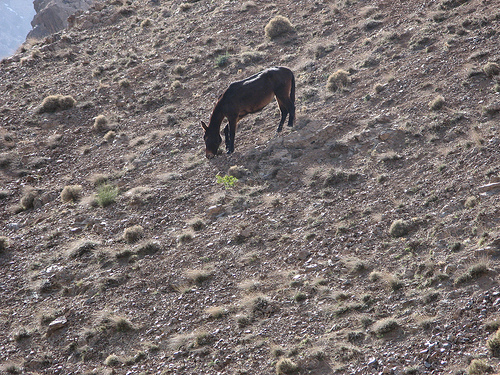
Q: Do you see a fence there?
A: No, there are no fences.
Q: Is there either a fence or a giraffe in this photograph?
A: No, there are no fences or giraffes.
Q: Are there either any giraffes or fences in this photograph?
A: No, there are no fences or giraffes.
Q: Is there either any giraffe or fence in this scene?
A: No, there are no fences or giraffes.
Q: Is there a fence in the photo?
A: No, there are no fences.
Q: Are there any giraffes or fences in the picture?
A: No, there are no fences or giraffes.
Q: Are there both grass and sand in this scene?
A: No, there is grass but no sand.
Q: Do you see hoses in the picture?
A: No, there are no hoses.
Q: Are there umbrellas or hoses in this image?
A: No, there are no hoses or umbrellas.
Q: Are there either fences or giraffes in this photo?
A: No, there are no fences or giraffes.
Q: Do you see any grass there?
A: Yes, there is grass.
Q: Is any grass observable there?
A: Yes, there is grass.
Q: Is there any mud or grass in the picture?
A: Yes, there is grass.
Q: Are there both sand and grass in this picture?
A: No, there is grass but no sand.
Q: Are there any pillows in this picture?
A: No, there are no pillows.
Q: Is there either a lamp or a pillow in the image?
A: No, there are no pillows or lamps.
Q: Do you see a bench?
A: No, there are no benches.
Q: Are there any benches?
A: No, there are no benches.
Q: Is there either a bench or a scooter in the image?
A: No, there are no benches or scooters.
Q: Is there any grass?
A: Yes, there is grass.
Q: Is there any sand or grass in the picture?
A: Yes, there is grass.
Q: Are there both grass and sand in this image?
A: No, there is grass but no sand.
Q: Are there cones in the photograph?
A: No, there are no cones.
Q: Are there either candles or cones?
A: No, there are no cones or candles.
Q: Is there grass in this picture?
A: Yes, there is grass.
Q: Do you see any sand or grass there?
A: Yes, there is grass.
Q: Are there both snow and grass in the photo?
A: No, there is grass but no snow.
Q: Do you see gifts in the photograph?
A: No, there are no gifts.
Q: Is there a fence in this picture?
A: No, there are no fences.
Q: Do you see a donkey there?
A: Yes, there is a donkey.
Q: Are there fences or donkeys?
A: Yes, there is a donkey.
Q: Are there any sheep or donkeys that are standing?
A: Yes, the donkey is standing.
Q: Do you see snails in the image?
A: No, there are no snails.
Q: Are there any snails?
A: No, there are no snails.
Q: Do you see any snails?
A: No, there are no snails.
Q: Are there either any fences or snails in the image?
A: No, there are no snails or fences.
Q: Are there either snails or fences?
A: No, there are no snails or fences.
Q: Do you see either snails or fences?
A: No, there are no snails or fences.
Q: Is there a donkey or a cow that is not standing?
A: No, there is a donkey but it is standing.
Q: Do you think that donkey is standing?
A: Yes, the donkey is standing.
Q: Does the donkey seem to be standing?
A: Yes, the donkey is standing.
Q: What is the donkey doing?
A: The donkey is standing.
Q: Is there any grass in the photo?
A: Yes, there is grass.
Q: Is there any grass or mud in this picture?
A: Yes, there is grass.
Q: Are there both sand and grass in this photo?
A: No, there is grass but no sand.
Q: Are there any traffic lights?
A: No, there are no traffic lights.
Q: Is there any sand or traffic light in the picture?
A: No, there are no traffic lights or sand.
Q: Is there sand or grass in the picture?
A: Yes, there is grass.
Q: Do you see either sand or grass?
A: Yes, there is grass.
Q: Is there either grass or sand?
A: Yes, there is grass.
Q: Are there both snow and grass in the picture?
A: No, there is grass but no snow.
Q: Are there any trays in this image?
A: No, there are no trays.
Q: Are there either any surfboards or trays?
A: No, there are no trays or surfboards.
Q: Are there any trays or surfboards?
A: No, there are no trays or surfboards.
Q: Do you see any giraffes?
A: No, there are no giraffes.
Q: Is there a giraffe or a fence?
A: No, there are no giraffes or fences.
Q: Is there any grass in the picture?
A: Yes, there is grass.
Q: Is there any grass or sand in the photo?
A: Yes, there is grass.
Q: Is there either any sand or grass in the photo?
A: Yes, there is grass.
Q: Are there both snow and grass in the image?
A: No, there is grass but no snow.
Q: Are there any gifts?
A: No, there are no gifts.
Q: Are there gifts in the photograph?
A: No, there are no gifts.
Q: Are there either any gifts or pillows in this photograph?
A: No, there are no gifts or pillows.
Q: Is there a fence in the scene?
A: No, there are no fences.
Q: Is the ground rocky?
A: Yes, the ground is rocky.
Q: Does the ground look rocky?
A: Yes, the ground is rocky.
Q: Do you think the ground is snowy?
A: No, the ground is rocky.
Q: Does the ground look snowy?
A: No, the ground is rocky.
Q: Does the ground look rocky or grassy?
A: The ground is rocky.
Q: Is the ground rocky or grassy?
A: The ground is rocky.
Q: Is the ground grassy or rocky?
A: The ground is rocky.